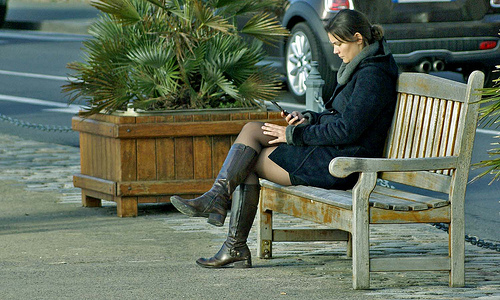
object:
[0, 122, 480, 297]
sidewalk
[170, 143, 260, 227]
boot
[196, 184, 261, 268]
boot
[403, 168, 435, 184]
wall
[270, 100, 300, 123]
phone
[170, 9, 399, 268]
bird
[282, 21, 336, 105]
tire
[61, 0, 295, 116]
plant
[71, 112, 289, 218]
box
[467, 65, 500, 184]
plant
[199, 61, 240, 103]
leaf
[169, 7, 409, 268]
women sitting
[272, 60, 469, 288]
bench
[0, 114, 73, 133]
chain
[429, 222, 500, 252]
chain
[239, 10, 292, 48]
leaf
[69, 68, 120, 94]
leaf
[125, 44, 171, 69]
leaf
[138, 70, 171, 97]
leaf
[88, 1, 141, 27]
leaf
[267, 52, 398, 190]
coat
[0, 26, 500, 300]
ground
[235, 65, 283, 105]
leaf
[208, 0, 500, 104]
vehicle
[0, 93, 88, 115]
line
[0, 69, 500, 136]
line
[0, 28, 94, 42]
line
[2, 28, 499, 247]
road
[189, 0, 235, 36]
leaf